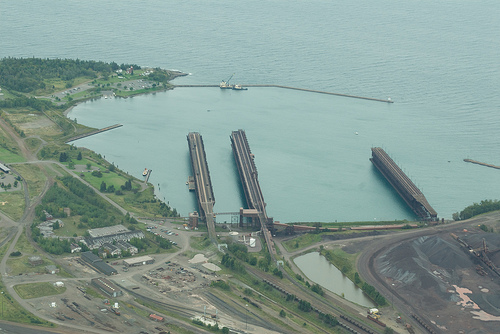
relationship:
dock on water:
[186, 132, 218, 223] [132, 89, 483, 189]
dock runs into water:
[229, 129, 267, 231] [2, 1, 499, 222]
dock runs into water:
[186, 132, 218, 223] [2, 1, 499, 222]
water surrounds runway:
[2, 1, 499, 222] [169, 79, 394, 104]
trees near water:
[37, 177, 165, 254] [2, 1, 499, 222]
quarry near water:
[373, 217, 498, 329] [2, 1, 499, 222]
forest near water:
[1, 55, 159, 92] [2, 1, 499, 222]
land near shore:
[24, 124, 73, 140] [59, 90, 107, 117]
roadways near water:
[184, 207, 304, 294] [2, 1, 499, 222]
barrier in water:
[163, 79, 394, 107] [2, 1, 499, 222]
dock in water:
[365, 143, 441, 219] [91, 26, 499, 209]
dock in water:
[227, 126, 267, 231] [91, 26, 499, 209]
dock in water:
[185, 125, 217, 223] [91, 26, 499, 209]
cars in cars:
[96, 219, 213, 256] [145, 224, 200, 248]